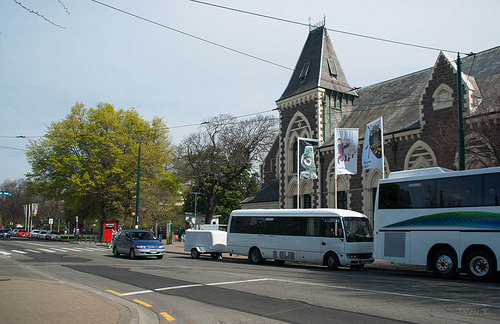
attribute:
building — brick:
[250, 22, 495, 225]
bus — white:
[369, 163, 499, 284]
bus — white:
[222, 203, 368, 272]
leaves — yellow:
[26, 102, 189, 214]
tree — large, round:
[23, 106, 185, 250]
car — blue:
[102, 225, 167, 264]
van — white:
[221, 194, 378, 282]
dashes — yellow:
[104, 281, 181, 321]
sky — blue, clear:
[0, 0, 498, 182]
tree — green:
[20, 97, 187, 236]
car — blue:
[98, 230, 172, 267]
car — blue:
[109, 223, 171, 262]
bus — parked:
[341, 174, 478, 259]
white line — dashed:
[131, 272, 275, 301]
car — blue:
[111, 227, 164, 260]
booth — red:
[99, 220, 112, 242]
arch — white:
[397, 137, 438, 172]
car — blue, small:
[113, 227, 167, 259]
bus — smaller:
[221, 207, 373, 270]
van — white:
[184, 206, 375, 271]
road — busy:
[2, 231, 498, 318]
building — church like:
[241, 16, 496, 216]